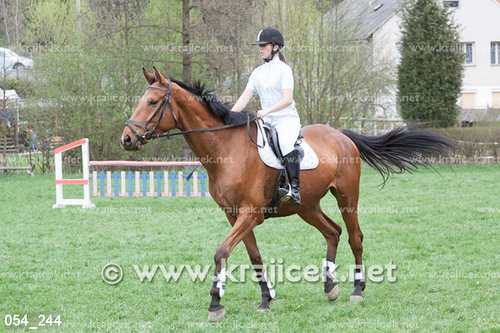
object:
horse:
[113, 60, 455, 312]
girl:
[229, 27, 300, 206]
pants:
[269, 114, 301, 184]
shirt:
[246, 57, 301, 120]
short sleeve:
[282, 60, 295, 91]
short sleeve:
[244, 73, 254, 93]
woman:
[230, 24, 303, 209]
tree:
[390, 2, 462, 127]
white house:
[367, 6, 500, 126]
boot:
[276, 147, 303, 204]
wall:
[440, 0, 498, 95]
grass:
[3, 176, 497, 331]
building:
[284, 0, 493, 142]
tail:
[340, 118, 461, 184]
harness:
[125, 79, 262, 144]